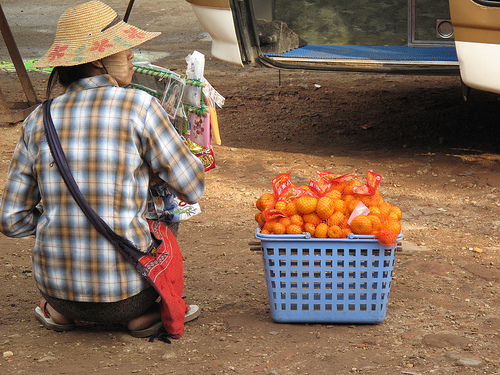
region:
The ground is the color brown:
[218, 328, 495, 372]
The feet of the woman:
[123, 299, 205, 344]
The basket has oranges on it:
[241, 155, 421, 326]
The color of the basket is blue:
[259, 231, 392, 333]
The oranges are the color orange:
[253, 165, 405, 246]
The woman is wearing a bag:
[26, 98, 202, 345]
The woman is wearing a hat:
[25, 0, 167, 76]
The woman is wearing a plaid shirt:
[11, 88, 176, 272]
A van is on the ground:
[209, 14, 499, 84]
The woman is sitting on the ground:
[15, 7, 265, 356]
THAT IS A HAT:
[31, 9, 142, 79]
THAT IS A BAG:
[104, 234, 185, 321]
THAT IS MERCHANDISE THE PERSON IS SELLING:
[139, 68, 204, 162]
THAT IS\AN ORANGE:
[314, 184, 339, 223]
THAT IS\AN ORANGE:
[286, 208, 306, 228]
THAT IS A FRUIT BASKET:
[275, 236, 382, 316]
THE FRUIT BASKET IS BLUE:
[276, 236, 382, 325]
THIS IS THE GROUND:
[226, 319, 266, 346]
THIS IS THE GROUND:
[424, 219, 461, 316]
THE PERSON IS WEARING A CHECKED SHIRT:
[97, 156, 127, 216]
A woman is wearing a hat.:
[22, 3, 140, 75]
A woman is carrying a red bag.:
[73, 193, 203, 319]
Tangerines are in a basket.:
[263, 178, 420, 308]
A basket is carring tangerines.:
[258, 202, 425, 352]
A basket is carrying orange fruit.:
[266, 173, 393, 324]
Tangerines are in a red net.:
[266, 179, 413, 244]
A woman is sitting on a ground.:
[37, 49, 137, 349]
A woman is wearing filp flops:
[23, 284, 104, 348]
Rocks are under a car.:
[338, 99, 480, 166]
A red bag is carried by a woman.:
[39, 101, 207, 363]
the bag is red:
[133, 210, 208, 315]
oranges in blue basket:
[264, 162, 406, 352]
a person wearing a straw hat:
[23, 8, 198, 333]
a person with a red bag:
[31, 3, 201, 336]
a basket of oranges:
[253, 180, 398, 323]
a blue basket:
[257, 229, 396, 325]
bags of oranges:
[248, 170, 395, 240]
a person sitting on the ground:
[32, 4, 197, 324]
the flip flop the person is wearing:
[130, 305, 197, 330]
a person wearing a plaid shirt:
[18, 50, 196, 335]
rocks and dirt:
[407, 189, 498, 316]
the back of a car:
[208, 5, 498, 74]